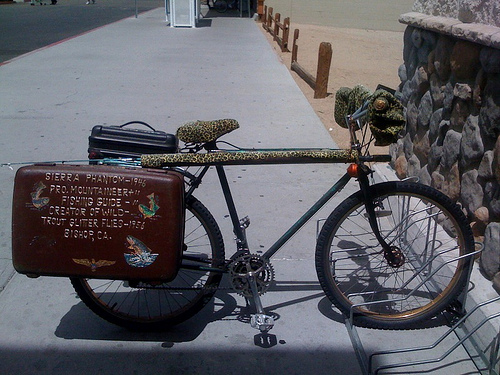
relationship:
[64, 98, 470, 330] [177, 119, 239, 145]
bicycle has seat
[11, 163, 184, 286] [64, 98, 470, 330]
suitcase on side of bicycle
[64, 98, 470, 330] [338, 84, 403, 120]
bicycle has handlebars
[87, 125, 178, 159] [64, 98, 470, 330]
case hanging on side of bicycle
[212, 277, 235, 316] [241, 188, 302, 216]
shadow on top of pavement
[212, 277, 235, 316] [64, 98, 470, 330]
shadow of bicycle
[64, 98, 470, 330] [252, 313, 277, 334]
bicycle has pedal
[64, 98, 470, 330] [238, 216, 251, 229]
bicycle has pedal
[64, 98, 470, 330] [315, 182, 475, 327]
bicycle has tire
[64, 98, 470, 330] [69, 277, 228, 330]
bicycle has tire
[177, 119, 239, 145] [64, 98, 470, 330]
seat on top of bicycle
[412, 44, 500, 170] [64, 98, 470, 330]
rock wall in front of bicycle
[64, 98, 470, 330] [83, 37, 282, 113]
bicycle on top of sidewalk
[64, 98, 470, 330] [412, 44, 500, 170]
bicycle in front of rock wall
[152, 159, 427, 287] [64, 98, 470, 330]
right side of bicycle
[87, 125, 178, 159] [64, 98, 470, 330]
case hanging on back of bicycle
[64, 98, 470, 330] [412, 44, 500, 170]
bicycle next to rock wall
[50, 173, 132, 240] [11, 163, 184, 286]
words on side of suitcase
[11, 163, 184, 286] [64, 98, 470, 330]
suitcase hanging on bicycle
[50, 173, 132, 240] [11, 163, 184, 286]
words are on top of suitcase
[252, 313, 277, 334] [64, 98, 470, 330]
pedal of bicycle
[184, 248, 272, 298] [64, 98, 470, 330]
gears of bicycle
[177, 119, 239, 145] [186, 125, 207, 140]
seat has design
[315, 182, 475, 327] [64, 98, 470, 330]
tire of bicycle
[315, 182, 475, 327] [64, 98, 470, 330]
tire on front of bicycle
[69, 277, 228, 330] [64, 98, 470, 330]
tire on back of bicycle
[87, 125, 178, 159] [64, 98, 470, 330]
case behind bicycle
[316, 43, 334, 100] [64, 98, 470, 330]
pole behind bicycle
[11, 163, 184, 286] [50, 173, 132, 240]
suitcase has words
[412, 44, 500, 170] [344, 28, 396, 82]
rock wall along beach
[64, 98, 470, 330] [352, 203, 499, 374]
bicycle parked at bike rack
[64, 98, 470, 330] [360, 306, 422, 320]
bicycle has rim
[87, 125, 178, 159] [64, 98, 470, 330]
case attached to bicycle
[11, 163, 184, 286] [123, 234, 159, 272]
suitcase has stickers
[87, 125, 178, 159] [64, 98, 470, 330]
case on side of bicycle